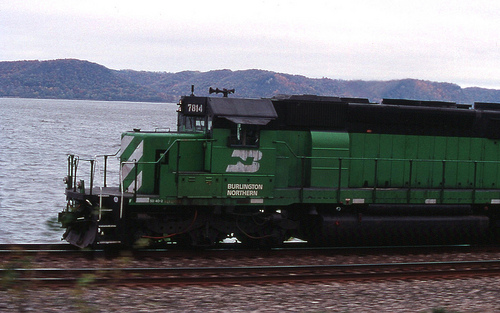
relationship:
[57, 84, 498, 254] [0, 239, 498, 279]
train on tracks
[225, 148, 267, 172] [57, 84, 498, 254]
sign on train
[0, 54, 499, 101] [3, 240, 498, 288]
hills near tracks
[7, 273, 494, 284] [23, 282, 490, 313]
grayish brown train tracks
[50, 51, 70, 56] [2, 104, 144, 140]
white and gray clouds against sky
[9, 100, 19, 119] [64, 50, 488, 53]
white and gray clouds against sky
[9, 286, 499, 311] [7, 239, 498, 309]
stones alongside tracks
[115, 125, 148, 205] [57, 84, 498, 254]
head of train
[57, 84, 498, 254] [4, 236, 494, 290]
train moving on tracks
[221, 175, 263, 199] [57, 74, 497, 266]
writing on side of train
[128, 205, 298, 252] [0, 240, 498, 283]
wheels on track